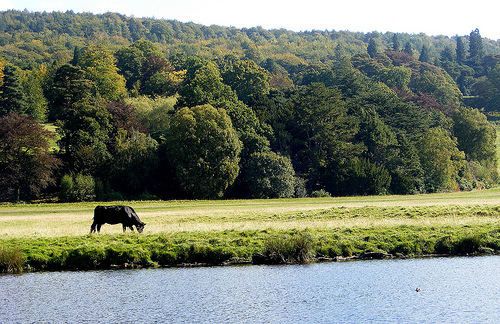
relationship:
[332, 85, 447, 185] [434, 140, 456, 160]
trees have leaves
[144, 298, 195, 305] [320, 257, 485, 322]
ripples in water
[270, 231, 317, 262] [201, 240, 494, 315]
bush growing beside river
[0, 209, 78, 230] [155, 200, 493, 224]
grass growing in field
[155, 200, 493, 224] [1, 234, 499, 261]
field on shore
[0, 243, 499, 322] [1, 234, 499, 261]
river has shore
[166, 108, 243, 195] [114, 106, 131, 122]
tree has leaves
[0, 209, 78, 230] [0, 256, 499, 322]
grass growing by water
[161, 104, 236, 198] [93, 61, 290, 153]
tree has leaves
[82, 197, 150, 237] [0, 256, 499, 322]
cow standing by water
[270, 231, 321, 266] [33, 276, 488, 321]
bush growing by water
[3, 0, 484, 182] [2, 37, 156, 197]
forest has trees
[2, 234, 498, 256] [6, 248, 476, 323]
embankment next to water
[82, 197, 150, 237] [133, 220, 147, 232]
cow has head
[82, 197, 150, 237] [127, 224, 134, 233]
cow has legs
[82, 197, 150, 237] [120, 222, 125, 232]
cow has legs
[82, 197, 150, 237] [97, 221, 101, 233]
cow has legs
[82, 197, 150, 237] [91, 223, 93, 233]
cow has legs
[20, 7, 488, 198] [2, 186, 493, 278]
trees behind field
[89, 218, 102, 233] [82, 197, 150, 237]
hind leg of cow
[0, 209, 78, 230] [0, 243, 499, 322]
grass on side of river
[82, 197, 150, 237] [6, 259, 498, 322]
cow grazing by lake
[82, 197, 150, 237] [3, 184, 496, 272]
cow on ranch